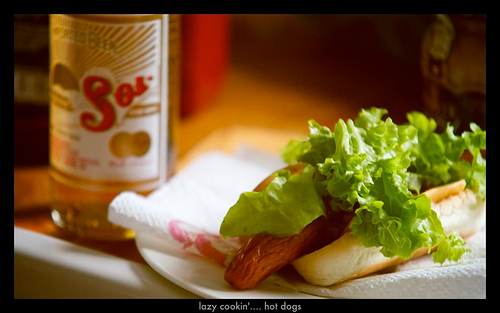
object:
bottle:
[39, 12, 186, 244]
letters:
[73, 70, 119, 135]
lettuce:
[220, 107, 489, 264]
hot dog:
[220, 207, 346, 290]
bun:
[293, 190, 474, 286]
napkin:
[105, 183, 220, 253]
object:
[180, 13, 235, 118]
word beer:
[127, 101, 161, 118]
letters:
[196, 301, 203, 311]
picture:
[1, 3, 498, 313]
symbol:
[100, 125, 157, 161]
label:
[39, 15, 171, 191]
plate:
[150, 248, 227, 290]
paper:
[177, 121, 284, 159]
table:
[19, 65, 489, 293]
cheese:
[425, 175, 469, 203]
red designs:
[165, 217, 239, 267]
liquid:
[51, 15, 175, 238]